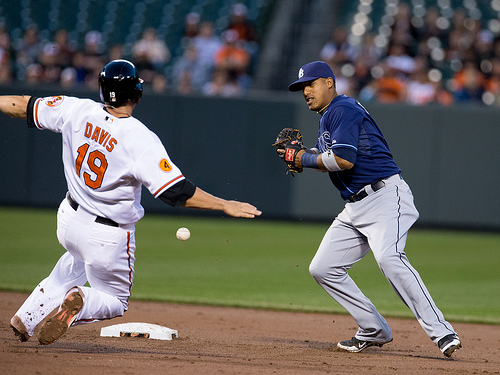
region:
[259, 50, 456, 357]
Baseball player on the field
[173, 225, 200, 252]
ball in the air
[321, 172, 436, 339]
player wearing gray pants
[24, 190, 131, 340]
player wearing white pants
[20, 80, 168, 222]
player wearing a white jersey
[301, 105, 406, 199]
player wearing a blue jersey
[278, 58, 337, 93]
player wearing a blue hat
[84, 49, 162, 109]
player wearing a black helmet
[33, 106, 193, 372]
player sliding in to the base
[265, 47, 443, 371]
player throwing the ball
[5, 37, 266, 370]
Man dressed in white baseball uniform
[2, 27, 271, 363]
Team member running for a base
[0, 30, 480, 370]
Men playing baseball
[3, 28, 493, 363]
Baseball players during a game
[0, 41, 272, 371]
Man sliding to base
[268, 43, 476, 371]
Baseball player dressed in a blue and gray uniform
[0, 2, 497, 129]
A stadium full of spectators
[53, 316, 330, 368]
Brown muddy ground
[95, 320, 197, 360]
White baseball base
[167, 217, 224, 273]
Baseball flying through the air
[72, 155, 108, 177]
the numbers are orange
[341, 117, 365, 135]
the shirt is blue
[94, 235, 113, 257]
the pants are white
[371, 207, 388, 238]
the pants are gray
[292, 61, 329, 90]
he is wearing a hat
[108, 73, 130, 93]
the helmet is black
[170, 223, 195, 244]
the ball is white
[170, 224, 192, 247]
the ball is in the air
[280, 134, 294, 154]
the glove is black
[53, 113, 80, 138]
the shirt is white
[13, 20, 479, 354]
a professional baseball game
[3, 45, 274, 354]
a player sliding into base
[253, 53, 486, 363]
a player going for the baseball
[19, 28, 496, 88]
the spectators at a baseball game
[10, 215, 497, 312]
the grass of a baseball field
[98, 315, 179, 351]
the base the runner is going to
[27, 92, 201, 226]
the jersey of a baseball player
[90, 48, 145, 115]
a blue batter's helmet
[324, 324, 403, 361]
a Nike baseball cleat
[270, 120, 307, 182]
a leather baseball glove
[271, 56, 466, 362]
A person playing baseball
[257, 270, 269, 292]
Part of the green grass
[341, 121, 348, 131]
Part of the blue shirt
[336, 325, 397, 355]
The right foot of the person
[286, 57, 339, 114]
The head of the person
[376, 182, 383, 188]
Part of the black belt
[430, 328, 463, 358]
The left foot of the person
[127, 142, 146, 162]
Part of the white shirt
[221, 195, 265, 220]
The right hand of the person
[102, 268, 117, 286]
Part of the pants